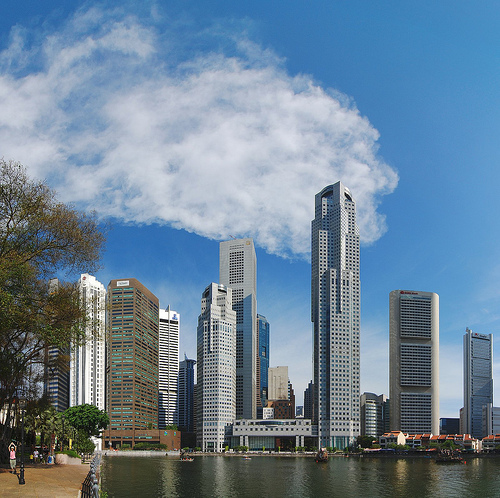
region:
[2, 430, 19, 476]
a person wearing a pink shirt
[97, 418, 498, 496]
a waterfront walkway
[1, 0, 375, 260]
a large white cloud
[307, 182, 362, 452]
a high-rise building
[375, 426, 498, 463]
a building with an orange roof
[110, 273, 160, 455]
a brown high rise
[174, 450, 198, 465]
a boat on the water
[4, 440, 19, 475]
a person stretching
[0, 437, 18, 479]
a person walking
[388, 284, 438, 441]
a high-rise building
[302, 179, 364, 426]
large gray building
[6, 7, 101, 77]
white clouds in blue sky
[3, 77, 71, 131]
white clouds in blue sky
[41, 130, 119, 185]
white clouds in blue sky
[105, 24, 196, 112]
white clouds in blue sky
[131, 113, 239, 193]
white clouds in blue sky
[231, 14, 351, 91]
white clouds in blue sky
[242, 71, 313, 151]
white clouds in blue sky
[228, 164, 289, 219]
white clouds in blue sky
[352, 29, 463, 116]
white clouds in blue sky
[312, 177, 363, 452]
a tall building in distance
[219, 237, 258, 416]
a tall building in distance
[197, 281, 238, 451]
a tall building in distance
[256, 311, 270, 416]
a tall building in distance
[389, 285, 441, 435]
a tall building in distance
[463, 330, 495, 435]
a tall building in distance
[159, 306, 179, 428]
a tall building in distance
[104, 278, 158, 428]
a tall building in distance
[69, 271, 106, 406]
a tall building in distance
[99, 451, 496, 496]
a body of water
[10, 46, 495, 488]
towering skyscrapers along a harbor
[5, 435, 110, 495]
people on walkway on side of water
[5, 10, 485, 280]
large white cloud over blue sky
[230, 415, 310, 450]
wide elevated building on supports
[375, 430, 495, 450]
low buildings with red roofs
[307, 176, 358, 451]
tall building of different heights and angles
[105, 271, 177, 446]
brown building in front of gray building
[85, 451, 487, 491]
pilings on side of dark water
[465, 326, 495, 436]
building constructed of vertical panels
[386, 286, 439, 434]
smooth sides on facade of three grids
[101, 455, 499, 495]
dark water near city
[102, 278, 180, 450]
large brown building with green windows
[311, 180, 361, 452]
tallest silver building with windows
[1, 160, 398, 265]
large white puffy clouds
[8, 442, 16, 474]
person wearing pink shirt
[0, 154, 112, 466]
large tree losing leaves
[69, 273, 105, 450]
tallet white building near water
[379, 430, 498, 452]
group of buildings with red roofs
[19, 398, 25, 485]
black metal pole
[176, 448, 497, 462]
group of boats on water